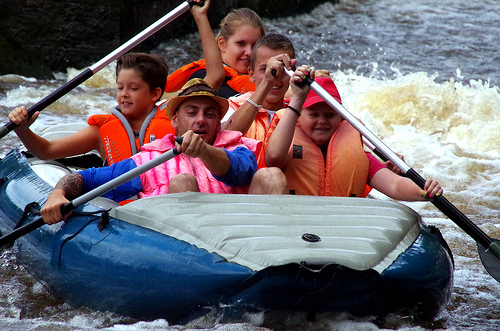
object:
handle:
[0, 137, 196, 245]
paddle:
[291, 61, 499, 285]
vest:
[87, 105, 176, 166]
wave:
[0, 61, 500, 330]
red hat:
[294, 73, 340, 110]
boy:
[6, 52, 177, 167]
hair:
[114, 52, 169, 103]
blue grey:
[108, 214, 245, 275]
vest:
[256, 109, 369, 200]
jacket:
[72, 130, 255, 199]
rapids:
[0, 59, 499, 331]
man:
[38, 77, 289, 226]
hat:
[164, 77, 231, 121]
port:
[300, 233, 320, 243]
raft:
[0, 118, 456, 325]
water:
[0, 0, 499, 330]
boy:
[262, 64, 442, 204]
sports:
[2, 3, 499, 330]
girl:
[161, 6, 267, 100]